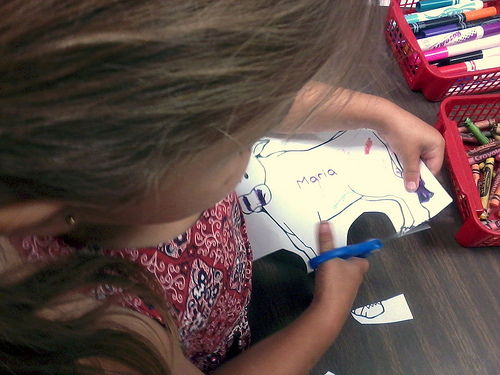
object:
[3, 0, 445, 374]
girl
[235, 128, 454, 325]
paper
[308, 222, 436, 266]
pair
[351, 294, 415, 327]
piece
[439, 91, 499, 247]
bin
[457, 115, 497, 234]
crayons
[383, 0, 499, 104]
bin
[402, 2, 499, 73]
markers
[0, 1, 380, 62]
top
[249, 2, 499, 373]
table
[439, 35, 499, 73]
marker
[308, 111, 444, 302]
hands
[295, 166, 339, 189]
maria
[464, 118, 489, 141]
crayon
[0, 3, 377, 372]
hair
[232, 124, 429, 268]
drawing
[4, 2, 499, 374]
picture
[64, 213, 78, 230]
earring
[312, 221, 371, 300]
hand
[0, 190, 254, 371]
shirt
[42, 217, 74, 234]
ear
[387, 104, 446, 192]
hand